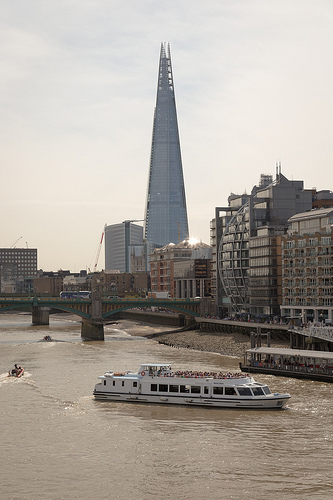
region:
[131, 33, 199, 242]
large building in a city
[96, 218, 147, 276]
large building in a city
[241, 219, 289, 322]
large building in a city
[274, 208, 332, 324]
large building in a city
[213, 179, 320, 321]
large building in a city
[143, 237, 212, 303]
large building in a city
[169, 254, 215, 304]
large building in a city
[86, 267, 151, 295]
large building in a city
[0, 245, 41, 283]
large building in a city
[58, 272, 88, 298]
large building in a city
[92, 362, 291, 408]
a white ship on a river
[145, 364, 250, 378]
people standing on the upper level of a white ship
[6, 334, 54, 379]
two small boats on the river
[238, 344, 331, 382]
a boat on the other side of the white ship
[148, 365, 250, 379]
passengers on top of a white ship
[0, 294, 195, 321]
a green and brown bridge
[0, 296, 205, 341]
a bridge over the river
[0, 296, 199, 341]
a green and brown bridge for drivers to cross the river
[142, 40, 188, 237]
a tall skyscraper near the river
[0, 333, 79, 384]
people riding two small boats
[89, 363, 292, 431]
Large white boat lined in black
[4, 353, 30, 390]
One small boat on water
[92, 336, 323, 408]
Two large boats on water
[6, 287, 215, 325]
One green bridge with water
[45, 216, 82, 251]
Clear sunny day no clouds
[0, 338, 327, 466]
Water surrounding boats and bridge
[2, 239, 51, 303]
Small brown building in background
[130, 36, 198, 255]
Large tall building in background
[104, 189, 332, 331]
Smaller buildings with windows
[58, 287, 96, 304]
Blue and white bus on bridge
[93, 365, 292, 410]
boat floating on a river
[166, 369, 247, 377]
people standing on a boat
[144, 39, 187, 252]
tall cone shaped skyscaper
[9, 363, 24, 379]
small boat on the river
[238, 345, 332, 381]
tour boat full of people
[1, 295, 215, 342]
bridge over the river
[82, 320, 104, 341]
concrete support for the bridge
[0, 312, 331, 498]
river with boats on it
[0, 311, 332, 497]
river next to a city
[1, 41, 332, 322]
buildings on the other side of the river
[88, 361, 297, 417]
Passenger filled ferry boat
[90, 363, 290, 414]
Passenger dense sightseeing boat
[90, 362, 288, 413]
Passenger filled sightseeing boat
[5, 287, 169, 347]
Decorative concrete automobile bridge over a river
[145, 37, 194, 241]
Conal shaped sky scraper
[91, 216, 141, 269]
Two industrial cranes working on a sky scraper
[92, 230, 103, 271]
Red and white industrial crane arm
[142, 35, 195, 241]
Pyramid shaped skyscraper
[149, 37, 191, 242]
Skyscraper in the shape of a narrow pyramid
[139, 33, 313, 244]
Pyramid shaped skyscraper towering above all other building in the city